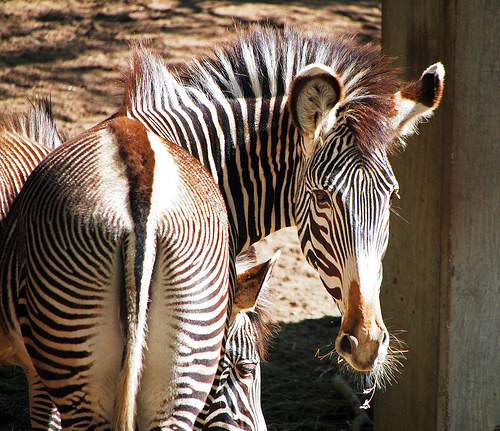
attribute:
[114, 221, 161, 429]
tail — black, white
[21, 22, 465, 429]
zebra — striped, black, white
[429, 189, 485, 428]
pole — wooden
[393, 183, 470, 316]
enclosure — Zebra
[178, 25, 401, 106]
mane — black, white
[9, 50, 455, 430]
zebra — striped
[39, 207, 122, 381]
zebra's butt — striped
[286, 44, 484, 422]
zebra head — black striped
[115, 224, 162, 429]
zebra tail — black striped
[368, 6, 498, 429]
post — wooden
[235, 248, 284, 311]
zebra ear — brown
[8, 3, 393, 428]
ground — shadowed